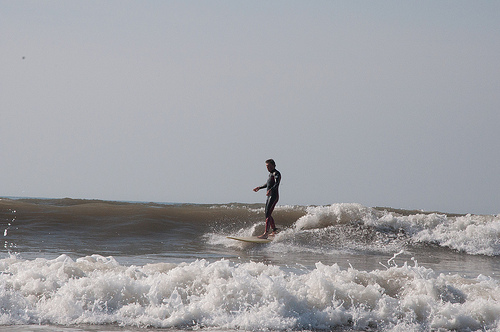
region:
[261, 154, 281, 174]
the head of a man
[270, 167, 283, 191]
the arm of a man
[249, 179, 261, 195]
the hand of a man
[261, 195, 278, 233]
the legs of a man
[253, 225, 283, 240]
the feet of the man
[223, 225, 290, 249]
a white surfboard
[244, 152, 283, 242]
a person on the surfboard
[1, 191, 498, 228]
the crest of a wave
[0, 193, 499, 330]
gray ocean water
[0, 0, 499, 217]
a gray sky overhead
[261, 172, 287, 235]
shiny black wet suit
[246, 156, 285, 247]
man standing on surfboard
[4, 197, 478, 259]
wave formed in ocean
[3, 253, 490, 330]
breaking wave on shoreline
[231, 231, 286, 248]
long ivory surf board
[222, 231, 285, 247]
surf board in ocean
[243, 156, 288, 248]
man riding wave in ocean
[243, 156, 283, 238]
man wearing black wetsuit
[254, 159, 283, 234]
man looking at water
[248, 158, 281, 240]
man watching wave break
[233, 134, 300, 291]
the man is surf boarding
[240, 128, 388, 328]
the man is surf boarding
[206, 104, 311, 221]
the man is surf boarding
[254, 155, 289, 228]
male surfer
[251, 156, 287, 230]
male surfer in ocean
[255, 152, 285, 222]
male surfer wearing wet suit in ocean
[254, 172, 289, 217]
male surfer wearing black wet suit in ocean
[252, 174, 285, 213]
male surfer wearing black wet suit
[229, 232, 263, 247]
surf board ridden by male surfer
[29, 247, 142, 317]
white and brown waves in ocean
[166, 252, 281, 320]
white and brown waves in ocean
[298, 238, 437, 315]
white and brown waves in ocean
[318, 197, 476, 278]
white and brown waves in ocean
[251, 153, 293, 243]
this is a man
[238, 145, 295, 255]
this is a human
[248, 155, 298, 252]
this is a surfer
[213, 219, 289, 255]
this is a surfboard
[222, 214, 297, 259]
this is a surf board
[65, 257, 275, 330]
this is white foam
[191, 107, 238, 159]
this is the sky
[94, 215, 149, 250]
this is the ocean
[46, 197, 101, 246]
this is a wave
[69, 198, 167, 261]
this is gray water